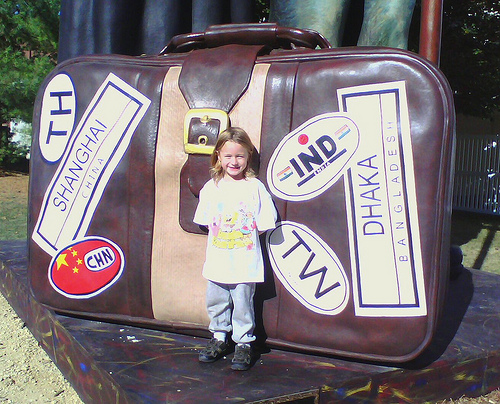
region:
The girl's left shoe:
[231, 342, 256, 375]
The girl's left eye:
[234, 152, 246, 159]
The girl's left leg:
[233, 284, 256, 341]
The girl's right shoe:
[196, 334, 229, 365]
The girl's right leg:
[203, 279, 232, 336]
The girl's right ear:
[213, 150, 223, 164]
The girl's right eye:
[224, 153, 233, 160]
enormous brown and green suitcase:
[20, 18, 463, 380]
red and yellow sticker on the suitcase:
[46, 233, 131, 300]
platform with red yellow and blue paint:
[2, 237, 498, 402]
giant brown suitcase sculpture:
[29, 22, 445, 367]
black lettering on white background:
[270, 230, 337, 303]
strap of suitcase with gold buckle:
[172, 65, 250, 231]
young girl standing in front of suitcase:
[189, 129, 266, 372]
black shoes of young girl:
[196, 336, 252, 371]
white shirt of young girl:
[195, 178, 275, 283]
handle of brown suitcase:
[153, 19, 327, 49]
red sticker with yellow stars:
[42, 242, 122, 298]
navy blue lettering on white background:
[273, 134, 351, 184]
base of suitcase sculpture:
[3, 239, 498, 401]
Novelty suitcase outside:
[10, 3, 460, 372]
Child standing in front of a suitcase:
[187, 107, 287, 384]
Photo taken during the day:
[15, 13, 485, 384]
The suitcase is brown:
[0, 50, 444, 372]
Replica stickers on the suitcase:
[0, 58, 462, 333]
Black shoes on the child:
[181, 333, 272, 377]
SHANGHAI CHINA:
[54, 103, 134, 217]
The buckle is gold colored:
[177, 103, 222, 157]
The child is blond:
[212, 133, 257, 193]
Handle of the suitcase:
[140, 13, 341, 67]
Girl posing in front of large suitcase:
[27, 45, 457, 337]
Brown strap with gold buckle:
[178, 48, 258, 146]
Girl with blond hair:
[210, 123, 256, 180]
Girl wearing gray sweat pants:
[201, 124, 263, 343]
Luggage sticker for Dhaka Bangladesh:
[355, 77, 408, 320]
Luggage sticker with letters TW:
[272, 222, 347, 307]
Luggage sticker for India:
[270, 107, 360, 195]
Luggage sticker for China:
[51, 233, 127, 298]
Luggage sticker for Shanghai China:
[49, 83, 145, 238]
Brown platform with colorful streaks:
[61, 330, 200, 391]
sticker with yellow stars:
[2, 225, 126, 358]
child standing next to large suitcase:
[29, 135, 449, 365]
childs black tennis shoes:
[150, 342, 251, 368]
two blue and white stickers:
[25, 96, 131, 198]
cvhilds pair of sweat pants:
[202, 283, 292, 333]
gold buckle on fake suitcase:
[138, 102, 233, 170]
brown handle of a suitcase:
[108, 26, 323, 66]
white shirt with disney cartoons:
[167, 186, 275, 276]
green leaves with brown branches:
[5, 7, 61, 122]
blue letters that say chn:
[27, 201, 147, 307]